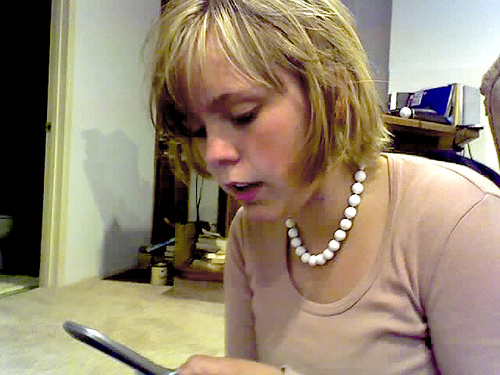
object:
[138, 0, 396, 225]
head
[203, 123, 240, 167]
nose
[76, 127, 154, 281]
shadow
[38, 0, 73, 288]
frame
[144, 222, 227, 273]
books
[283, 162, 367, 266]
necklace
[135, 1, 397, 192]
hair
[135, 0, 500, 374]
girl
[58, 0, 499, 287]
wall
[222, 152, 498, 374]
shirt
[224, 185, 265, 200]
lip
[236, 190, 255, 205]
lipstick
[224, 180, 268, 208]
mouth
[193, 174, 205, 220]
wire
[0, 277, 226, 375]
floor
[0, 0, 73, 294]
door way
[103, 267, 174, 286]
rug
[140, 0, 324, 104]
baangs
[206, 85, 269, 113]
eyebrow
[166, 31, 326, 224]
face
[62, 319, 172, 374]
cell phone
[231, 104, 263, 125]
eyes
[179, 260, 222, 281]
shelf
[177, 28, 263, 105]
forehead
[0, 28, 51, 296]
bathroom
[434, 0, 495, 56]
paint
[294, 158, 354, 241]
neck